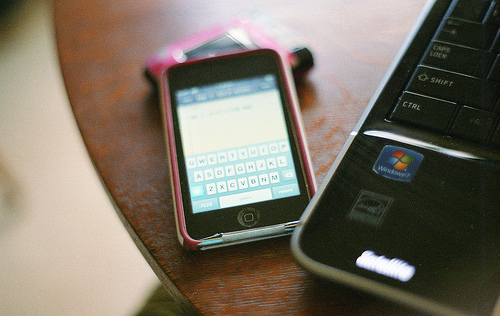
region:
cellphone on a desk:
[155, 46, 317, 277]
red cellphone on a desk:
[148, 40, 324, 254]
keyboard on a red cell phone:
[167, 132, 329, 220]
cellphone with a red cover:
[145, 40, 327, 267]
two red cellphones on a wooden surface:
[139, 9, 324, 259]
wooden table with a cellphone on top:
[88, 56, 225, 256]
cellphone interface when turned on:
[174, 74, 297, 216]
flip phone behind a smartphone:
[138, 13, 325, 258]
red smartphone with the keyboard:
[150, 53, 317, 261]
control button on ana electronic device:
[390, 86, 454, 127]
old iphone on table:
[146, 48, 330, 250]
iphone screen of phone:
[162, 72, 302, 213]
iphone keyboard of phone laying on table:
[181, 140, 305, 213]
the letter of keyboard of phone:
[248, 175, 258, 190]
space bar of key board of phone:
[215, 192, 284, 208]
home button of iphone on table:
[233, 203, 267, 232]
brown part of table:
[108, 149, 142, 159]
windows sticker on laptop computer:
[367, 141, 430, 181]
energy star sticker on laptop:
[344, 188, 399, 233]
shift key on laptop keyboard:
[405, 60, 490, 112]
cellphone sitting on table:
[150, 61, 323, 238]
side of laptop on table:
[285, 11, 480, 312]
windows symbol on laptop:
[375, 148, 425, 184]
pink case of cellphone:
[147, 78, 214, 255]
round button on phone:
[235, 205, 257, 226]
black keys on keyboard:
[385, 11, 478, 132]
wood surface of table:
[59, 2, 264, 302]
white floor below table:
[1, 56, 156, 312]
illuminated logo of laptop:
[350, 242, 414, 284]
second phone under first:
[141, 5, 322, 98]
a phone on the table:
[148, 50, 317, 276]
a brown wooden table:
[55, 10, 176, 288]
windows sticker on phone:
[373, 146, 420, 181]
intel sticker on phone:
[353, 190, 389, 230]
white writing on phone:
[351, 242, 418, 286]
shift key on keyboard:
[418, 66, 457, 92]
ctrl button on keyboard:
[398, 94, 428, 118]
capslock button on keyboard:
[423, 39, 455, 63]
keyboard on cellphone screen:
[192, 161, 275, 178]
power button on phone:
[238, 209, 259, 226]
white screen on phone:
[214, 124, 244, 138]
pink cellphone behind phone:
[190, 35, 260, 50]